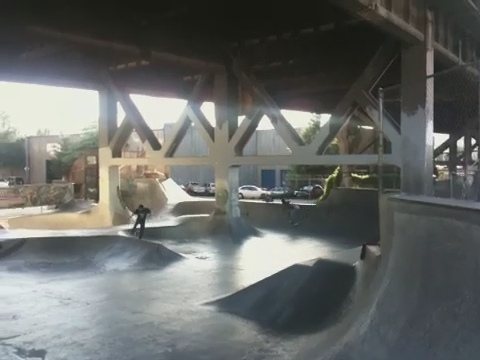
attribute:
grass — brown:
[58, 193, 110, 213]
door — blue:
[260, 168, 277, 191]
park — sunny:
[0, 123, 478, 358]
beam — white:
[398, 41, 433, 187]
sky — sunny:
[0, 79, 477, 149]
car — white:
[238, 180, 270, 204]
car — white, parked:
[223, 186, 301, 208]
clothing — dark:
[130, 206, 149, 237]